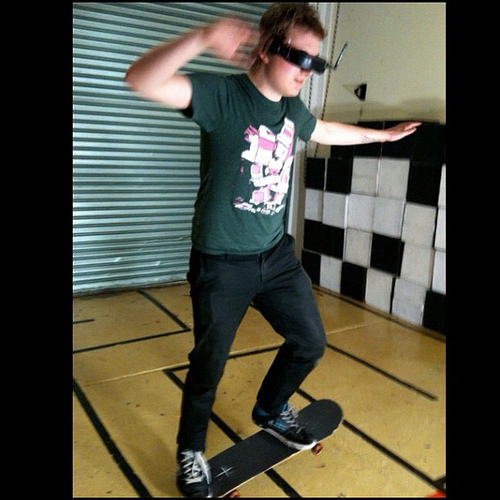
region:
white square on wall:
[303, 186, 322, 223]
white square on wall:
[320, 190, 352, 231]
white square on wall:
[354, 156, 376, 200]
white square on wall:
[373, 152, 408, 202]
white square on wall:
[346, 193, 373, 233]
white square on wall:
[368, 196, 399, 236]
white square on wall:
[344, 225, 370, 267]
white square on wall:
[315, 253, 343, 295]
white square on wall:
[367, 268, 394, 316]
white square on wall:
[391, 272, 424, 329]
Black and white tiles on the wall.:
[415, 192, 419, 327]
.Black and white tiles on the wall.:
[26, 245, 177, 400]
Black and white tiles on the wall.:
[253, 8, 301, 48]